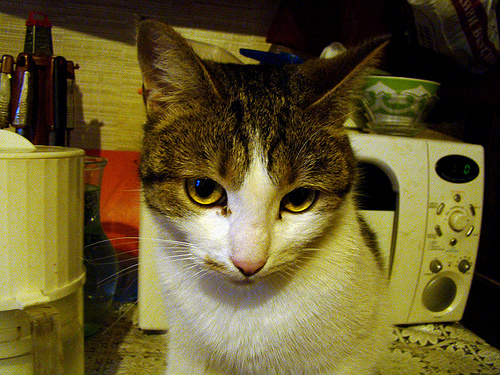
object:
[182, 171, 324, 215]
eyes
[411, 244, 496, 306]
button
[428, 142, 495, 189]
display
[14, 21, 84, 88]
grater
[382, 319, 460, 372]
flowers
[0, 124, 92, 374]
water pitcher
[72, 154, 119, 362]
vase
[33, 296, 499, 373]
countertop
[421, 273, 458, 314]
button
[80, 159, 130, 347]
vase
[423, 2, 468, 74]
bread bag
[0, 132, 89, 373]
processor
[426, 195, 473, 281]
buttons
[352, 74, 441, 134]
green bowl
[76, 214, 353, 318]
whiskers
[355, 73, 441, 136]
glass bowl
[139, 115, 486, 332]
microwave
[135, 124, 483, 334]
microwave oven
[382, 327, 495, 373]
counter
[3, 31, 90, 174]
utensils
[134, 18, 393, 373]
cat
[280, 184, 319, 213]
eye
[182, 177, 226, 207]
eye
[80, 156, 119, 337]
liquid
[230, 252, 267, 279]
nose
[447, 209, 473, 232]
dial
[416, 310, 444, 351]
table cloth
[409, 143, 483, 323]
control button